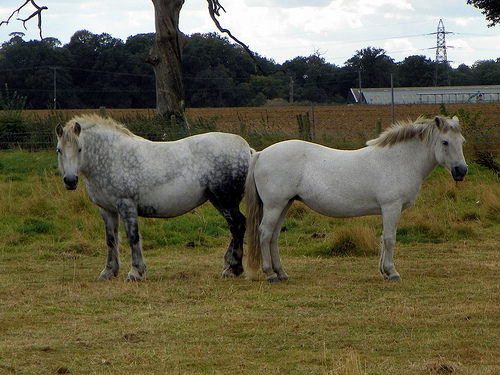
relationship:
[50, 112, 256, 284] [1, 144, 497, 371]
horse in field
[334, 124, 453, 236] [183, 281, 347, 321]
horse in field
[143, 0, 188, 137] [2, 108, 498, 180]
tree growing outside of fence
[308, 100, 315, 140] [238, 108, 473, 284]
post behind horse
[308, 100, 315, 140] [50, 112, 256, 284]
post behind horse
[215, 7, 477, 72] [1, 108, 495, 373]
cloudy over field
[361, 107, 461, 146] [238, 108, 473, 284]
mane of horse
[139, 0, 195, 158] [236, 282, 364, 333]
tree trunk in field